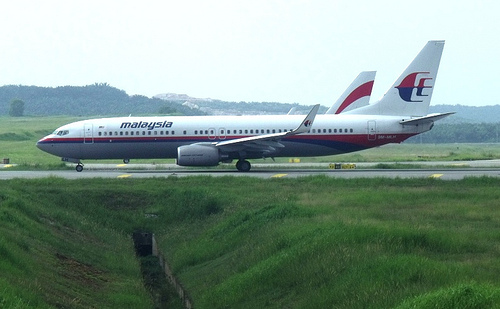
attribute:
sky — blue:
[9, 24, 344, 85]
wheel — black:
[237, 160, 249, 171]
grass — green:
[324, 216, 383, 244]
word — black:
[117, 118, 177, 135]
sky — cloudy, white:
[0, 0, 497, 105]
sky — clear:
[133, 2, 307, 107]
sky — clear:
[13, 1, 496, 83]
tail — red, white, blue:
[382, 34, 440, 114]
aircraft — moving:
[36, 39, 452, 185]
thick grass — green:
[0, 175, 499, 304]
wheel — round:
[75, 163, 85, 172]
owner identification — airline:
[116, 117, 177, 134]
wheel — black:
[235, 161, 256, 180]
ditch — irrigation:
[130, 230, 196, 307]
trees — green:
[1, 78, 203, 115]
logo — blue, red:
[393, 71, 432, 106]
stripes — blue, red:
[35, 132, 385, 145]